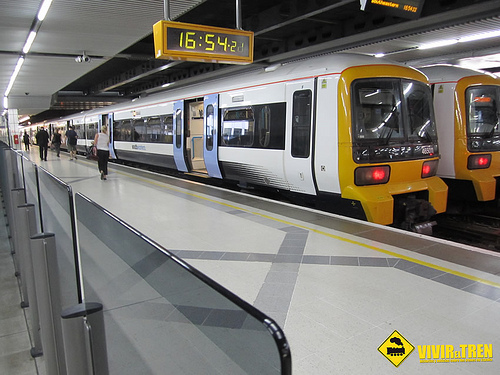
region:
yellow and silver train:
[21, 51, 456, 236]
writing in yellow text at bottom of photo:
[413, 338, 498, 367]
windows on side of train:
[114, 115, 171, 150]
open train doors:
[164, 90, 237, 181]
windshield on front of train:
[351, 72, 438, 158]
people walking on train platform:
[15, 118, 121, 186]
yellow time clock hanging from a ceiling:
[151, 20, 253, 63]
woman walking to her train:
[92, 125, 112, 180]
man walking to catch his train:
[64, 124, 77, 160]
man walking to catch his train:
[35, 126, 51, 161]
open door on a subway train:
[183, 98, 210, 175]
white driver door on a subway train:
[284, 77, 317, 197]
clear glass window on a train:
[348, 76, 440, 160]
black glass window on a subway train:
[217, 105, 287, 149]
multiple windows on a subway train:
[112, 114, 173, 144]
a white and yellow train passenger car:
[85, 52, 449, 229]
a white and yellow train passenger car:
[415, 64, 497, 213]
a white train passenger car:
[45, 111, 83, 158]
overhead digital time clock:
[150, 19, 252, 66]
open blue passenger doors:
[170, 92, 223, 180]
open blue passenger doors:
[95, 110, 116, 159]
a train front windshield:
[351, 76, 438, 161]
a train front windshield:
[464, 86, 499, 155]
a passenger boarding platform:
[6, 138, 496, 373]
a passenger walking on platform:
[92, 123, 111, 179]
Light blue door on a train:
[197, 95, 223, 177]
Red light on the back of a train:
[352, 164, 391, 187]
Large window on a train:
[347, 73, 441, 161]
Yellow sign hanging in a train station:
[152, 20, 254, 62]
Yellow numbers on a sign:
[173, 28, 245, 52]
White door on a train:
[281, 78, 319, 194]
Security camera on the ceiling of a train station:
[70, 48, 90, 62]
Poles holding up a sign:
[158, 2, 242, 27]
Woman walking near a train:
[92, 124, 112, 181]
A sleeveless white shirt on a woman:
[94, 131, 109, 151]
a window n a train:
[221, 107, 264, 157]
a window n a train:
[358, 80, 390, 144]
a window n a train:
[403, 75, 436, 151]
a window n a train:
[470, 83, 499, 124]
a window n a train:
[220, 102, 298, 147]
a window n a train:
[173, 112, 184, 139]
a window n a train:
[205, 107, 215, 144]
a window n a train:
[114, 116, 141, 141]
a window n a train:
[133, 118, 150, 146]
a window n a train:
[147, 118, 168, 158]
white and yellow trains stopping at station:
[17, 44, 493, 233]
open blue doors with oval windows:
[170, 92, 223, 180]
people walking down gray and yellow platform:
[19, 119, 498, 366]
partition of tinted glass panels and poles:
[3, 141, 292, 368]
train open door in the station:
[171, 96, 231, 176]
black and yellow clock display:
[167, 28, 248, 55]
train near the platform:
[18, 64, 451, 232]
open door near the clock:
[181, 97, 210, 174]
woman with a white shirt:
[87, 121, 118, 177]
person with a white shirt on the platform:
[89, 120, 115, 181]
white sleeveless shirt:
[96, 129, 111, 152]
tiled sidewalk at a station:
[7, 130, 499, 372]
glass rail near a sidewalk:
[5, 140, 292, 373]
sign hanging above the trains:
[362, 1, 422, 18]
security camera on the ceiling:
[69, 50, 94, 67]